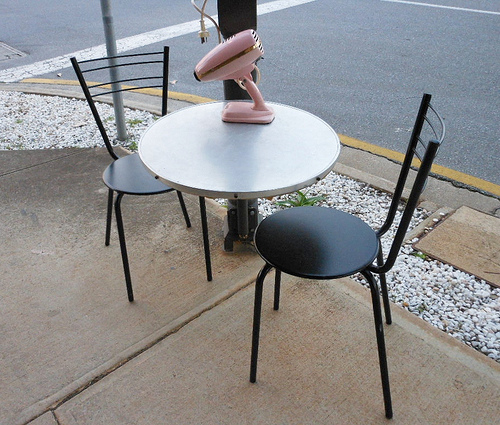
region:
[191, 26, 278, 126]
pink electrical device on a table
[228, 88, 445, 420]
modern style black chair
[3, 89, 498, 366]
gravel next to the sidewalk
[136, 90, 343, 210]
white circular table outside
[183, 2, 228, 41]
white electrical cord hanging on a pole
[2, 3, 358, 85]
white line on the road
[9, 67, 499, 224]
yellow line on edge of the road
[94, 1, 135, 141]
steel pole in the ground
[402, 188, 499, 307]
sewer drain in the street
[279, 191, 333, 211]
weed poking through the gravel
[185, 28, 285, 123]
pink hairdryer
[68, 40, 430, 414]
two black chairs at the table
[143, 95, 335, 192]
white table top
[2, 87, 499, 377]
white gravel around the sidewalk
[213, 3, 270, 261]
utility pole next to the table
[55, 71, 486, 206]
yellow line painted on the street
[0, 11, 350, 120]
white line on the street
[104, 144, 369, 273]
black seats of the chairs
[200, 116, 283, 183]
reflection on the table top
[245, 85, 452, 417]
a black metal chair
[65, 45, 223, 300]
a black metal chair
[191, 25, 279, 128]
a pink hair dryer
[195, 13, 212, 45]
the plug of a hair dryer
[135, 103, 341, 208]
a metal table on the street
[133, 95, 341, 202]
a metal table on the sidewalk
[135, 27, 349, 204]
a metal table with a hair dryer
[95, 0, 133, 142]
a metal pole in the floor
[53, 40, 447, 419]
two chairs and a table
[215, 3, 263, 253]
a large pole on the sidewalk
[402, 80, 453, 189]
PART OF BLACK CHAIR BACK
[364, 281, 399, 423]
PART OF BLACK CHAIR LEG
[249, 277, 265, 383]
PART OF BLACK CHAIR LEG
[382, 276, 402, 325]
PART OF BLACK CHAIR LEG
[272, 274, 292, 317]
PART OF BLACK CHAIR LEG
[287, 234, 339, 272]
PART OF BLACK CHAIR SEAT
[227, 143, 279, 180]
OART OF WHITE SERVING TABLE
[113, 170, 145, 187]
PART OF BLACK CHAIR SEAT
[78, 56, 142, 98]
PART OF BLACK CHAIR BACK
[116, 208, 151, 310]
PART OF BLACK CHAIR LEG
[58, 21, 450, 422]
two chairs around a table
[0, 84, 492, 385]
gravel along the edge of the sidewalk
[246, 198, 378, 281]
circular seat of the chair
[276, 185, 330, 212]
green weeds in the gravel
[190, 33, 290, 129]
object on the table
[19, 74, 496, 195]
yellow line along the side of the road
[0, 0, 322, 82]
thick white line on the road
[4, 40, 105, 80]
white paint is peeling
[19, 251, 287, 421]
crack in the sidewalk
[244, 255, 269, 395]
black leg on the chair